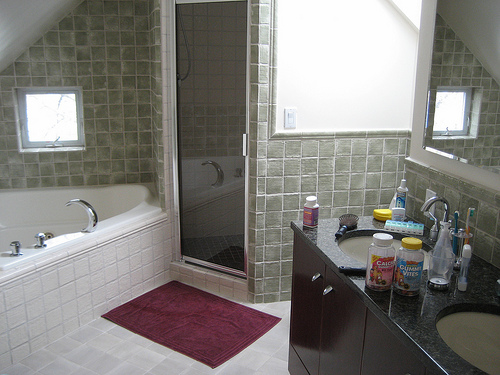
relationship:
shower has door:
[168, 0, 419, 300] [170, 7, 253, 269]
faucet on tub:
[65, 196, 92, 210] [0, 220, 58, 252]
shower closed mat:
[168, 0, 419, 300] [99, 280, 283, 367]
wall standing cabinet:
[82, 38, 145, 180] [285, 224, 411, 372]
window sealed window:
[432, 87, 482, 139] [11, 86, 83, 151]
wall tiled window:
[0, 0, 162, 182] [11, 86, 83, 151]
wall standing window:
[0, 0, 162, 182] [11, 86, 83, 151]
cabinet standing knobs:
[409, 295, 499, 366] [289, 269, 340, 299]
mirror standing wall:
[398, 1, 499, 212] [401, 8, 498, 228]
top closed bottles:
[400, 236, 423, 249] [396, 237, 426, 296]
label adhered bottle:
[373, 223, 432, 332] [365, 233, 393, 298]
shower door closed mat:
[169, 2, 252, 279] [99, 280, 283, 367]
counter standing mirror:
[291, 210, 494, 374] [419, 6, 497, 178]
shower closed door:
[168, 0, 419, 300] [176, 5, 253, 286]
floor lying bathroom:
[11, 280, 289, 375] [0, 0, 497, 369]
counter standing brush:
[291, 210, 494, 374] [335, 212, 358, 239]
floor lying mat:
[65, 306, 290, 375] [118, 280, 283, 367]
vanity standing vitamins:
[367, 267, 480, 344] [328, 180, 469, 350]